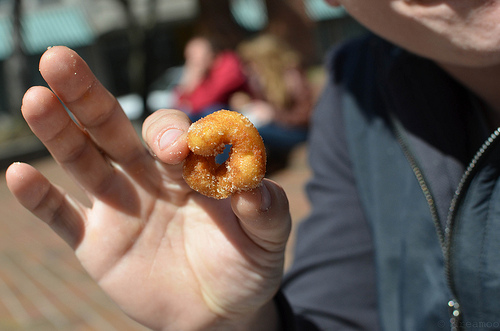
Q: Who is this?
A: A man.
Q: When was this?
A: Daytime.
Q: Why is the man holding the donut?
A: To eat it.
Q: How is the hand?
A: Raised.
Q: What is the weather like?
A: Sunny.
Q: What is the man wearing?
A: A jacket.